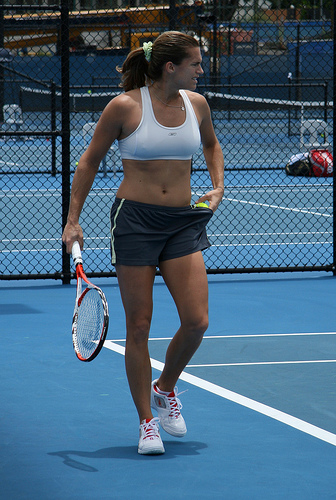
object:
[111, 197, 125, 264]
line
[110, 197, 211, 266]
shorts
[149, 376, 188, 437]
shoe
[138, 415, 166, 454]
shoe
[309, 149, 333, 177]
bag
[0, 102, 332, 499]
floor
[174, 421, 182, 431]
white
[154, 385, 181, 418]
red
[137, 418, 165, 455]
sneakers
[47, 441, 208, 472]
shadow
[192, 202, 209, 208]
tennis ball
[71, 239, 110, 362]
racket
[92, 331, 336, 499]
line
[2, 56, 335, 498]
tennis court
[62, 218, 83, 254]
hand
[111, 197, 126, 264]
stripe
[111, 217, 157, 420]
pins